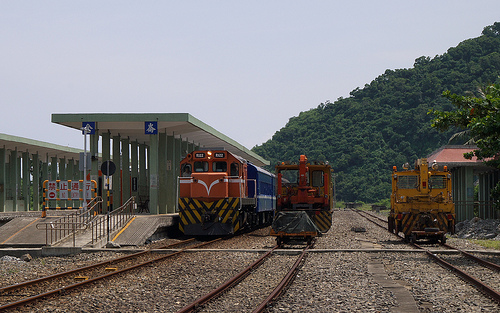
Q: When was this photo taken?
A: Daytime.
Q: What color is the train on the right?
A: Yellow.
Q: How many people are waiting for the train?
A: 0.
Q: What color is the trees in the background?
A: Green.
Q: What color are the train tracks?
A: Brown.